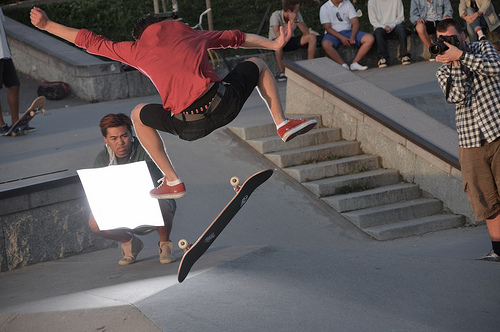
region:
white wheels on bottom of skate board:
[173, 234, 210, 252]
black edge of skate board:
[165, 265, 202, 290]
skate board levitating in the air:
[172, 170, 287, 288]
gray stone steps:
[286, 151, 435, 264]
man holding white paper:
[66, 157, 174, 229]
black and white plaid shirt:
[425, 60, 498, 151]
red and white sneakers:
[261, 116, 334, 147]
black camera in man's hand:
[417, 28, 456, 65]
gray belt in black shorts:
[166, 92, 250, 137]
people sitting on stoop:
[273, 5, 444, 68]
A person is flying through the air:
[20, 5, 353, 287]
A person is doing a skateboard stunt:
[21, 2, 366, 280]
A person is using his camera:
[398, 3, 494, 303]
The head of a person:
[100, 112, 128, 149]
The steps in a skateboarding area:
[292, 145, 362, 185]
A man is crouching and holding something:
[81, 100, 132, 268]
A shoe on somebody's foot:
[156, 237, 172, 264]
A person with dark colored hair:
[100, 110, 130, 153]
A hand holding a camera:
[430, 33, 460, 60]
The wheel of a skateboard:
[229, 175, 239, 187]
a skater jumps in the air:
[24, 4, 331, 290]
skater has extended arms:
[16, 1, 333, 213]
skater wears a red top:
[23, 5, 333, 202]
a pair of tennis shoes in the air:
[135, 112, 330, 203]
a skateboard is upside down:
[166, 157, 281, 285]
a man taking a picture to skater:
[31, 7, 498, 262]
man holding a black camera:
[421, 9, 498, 267]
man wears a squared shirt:
[422, 12, 495, 172]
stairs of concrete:
[241, 104, 470, 249]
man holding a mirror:
[71, 104, 185, 274]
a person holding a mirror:
[69, 105, 185, 277]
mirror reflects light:
[70, 155, 165, 234]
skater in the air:
[22, 2, 324, 203]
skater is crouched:
[25, 7, 342, 204]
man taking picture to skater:
[16, 0, 498, 265]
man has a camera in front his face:
[418, 18, 499, 263]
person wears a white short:
[313, 2, 380, 77]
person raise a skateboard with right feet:
[1, 21, 53, 143]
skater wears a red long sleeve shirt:
[24, 6, 334, 211]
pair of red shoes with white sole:
[142, 112, 334, 204]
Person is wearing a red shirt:
[67, 18, 251, 116]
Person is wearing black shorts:
[138, 56, 265, 143]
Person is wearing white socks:
[147, 111, 324, 201]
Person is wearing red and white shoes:
[148, 112, 319, 199]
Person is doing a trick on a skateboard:
[24, 6, 324, 287]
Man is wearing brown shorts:
[457, 129, 497, 223]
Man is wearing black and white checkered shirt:
[435, 38, 499, 153]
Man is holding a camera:
[425, 32, 466, 58]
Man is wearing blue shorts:
[319, 28, 374, 48]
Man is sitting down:
[310, 0, 374, 74]